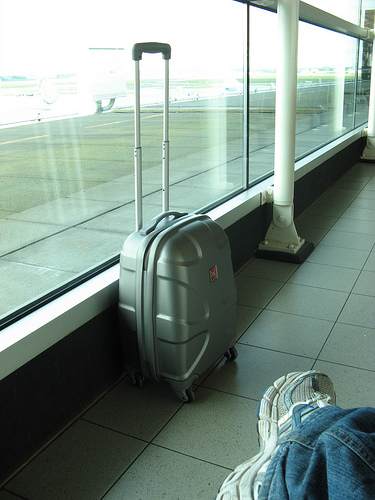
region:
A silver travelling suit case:
[107, 37, 245, 409]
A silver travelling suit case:
[99, 36, 246, 408]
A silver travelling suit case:
[112, 36, 242, 407]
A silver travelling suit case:
[114, 39, 243, 414]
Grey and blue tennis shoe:
[212, 359, 339, 498]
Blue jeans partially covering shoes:
[252, 400, 374, 499]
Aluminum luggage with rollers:
[113, 37, 241, 402]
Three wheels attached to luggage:
[132, 341, 241, 403]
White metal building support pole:
[253, 0, 315, 264]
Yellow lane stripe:
[0, 129, 53, 147]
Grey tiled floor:
[148, 395, 265, 468]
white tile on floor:
[17, 419, 149, 498]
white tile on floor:
[96, 443, 233, 498]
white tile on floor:
[82, 374, 183, 445]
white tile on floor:
[144, 385, 260, 468]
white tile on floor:
[310, 354, 373, 407]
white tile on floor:
[206, 342, 316, 408]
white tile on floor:
[234, 302, 261, 337]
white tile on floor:
[237, 306, 334, 364]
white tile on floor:
[315, 321, 373, 374]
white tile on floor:
[263, 282, 350, 328]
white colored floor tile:
[6, 420, 145, 498]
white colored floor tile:
[99, 444, 231, 498]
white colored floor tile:
[83, 373, 182, 442]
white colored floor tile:
[146, 385, 263, 471]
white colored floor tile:
[207, 341, 314, 405]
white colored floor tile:
[311, 360, 374, 414]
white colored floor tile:
[316, 321, 373, 372]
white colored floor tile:
[239, 307, 328, 361]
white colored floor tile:
[212, 309, 259, 329]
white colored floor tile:
[230, 273, 275, 309]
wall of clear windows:
[0, 1, 372, 322]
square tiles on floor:
[27, 162, 372, 497]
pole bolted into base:
[255, 0, 309, 263]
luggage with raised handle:
[118, 40, 238, 402]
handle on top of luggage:
[130, 210, 203, 248]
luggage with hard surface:
[119, 212, 234, 391]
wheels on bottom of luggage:
[127, 346, 238, 401]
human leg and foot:
[216, 369, 373, 499]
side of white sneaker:
[218, 370, 336, 499]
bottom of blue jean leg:
[260, 405, 373, 498]